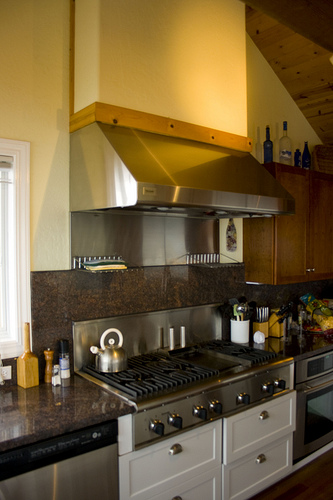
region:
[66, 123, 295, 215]
Silver range hood cover.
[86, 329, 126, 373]
Silver tea kettle with white handle.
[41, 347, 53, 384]
A brown pepper grinder.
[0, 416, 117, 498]
A black and silver dishwasher.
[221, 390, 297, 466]
A white drawer opened slightly.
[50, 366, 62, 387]
White salt shaker.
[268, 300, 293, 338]
A knife block with knives in it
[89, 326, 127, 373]
A stainless steel kettle with a white handle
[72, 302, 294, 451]
A large stainless steel cooktop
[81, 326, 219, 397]
A kettle sitting on a cooktop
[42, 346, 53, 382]
A wooden pepper mill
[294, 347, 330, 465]
A stainless steel oven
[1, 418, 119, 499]
A stainless steel dishwasher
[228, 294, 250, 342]
A white crock containing kitchen utensils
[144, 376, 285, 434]
Control knobs for a kitchen cooktop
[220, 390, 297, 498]
White kitchen drawers with stainless steel handles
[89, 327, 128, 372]
tea kettle on stove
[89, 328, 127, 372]
tea kettle is stainless steel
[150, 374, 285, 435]
black knobs on stove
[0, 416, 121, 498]
dishwasher is under counter top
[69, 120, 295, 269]
range hood over stove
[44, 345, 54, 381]
wooden grinder on counter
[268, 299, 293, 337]
knife block on counter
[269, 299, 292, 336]
knife block is wooden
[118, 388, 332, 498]
white wood under counter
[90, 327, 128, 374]
Silver kettle with white handle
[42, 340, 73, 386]
Salt and pepper shakers on the counter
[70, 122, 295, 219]
Fan over the stovetop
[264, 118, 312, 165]
Bottles above the cabinet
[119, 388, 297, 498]
White cabinets under the stove top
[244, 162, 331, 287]
Wooden cabinets over the oven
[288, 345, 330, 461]
Oven to the right of the stove top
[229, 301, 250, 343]
Utensils in a white jar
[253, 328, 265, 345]
White timer on the counter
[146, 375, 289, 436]
Control knobs for the stove top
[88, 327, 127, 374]
silver tea kettle with white handle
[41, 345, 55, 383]
brown wood pepper grinder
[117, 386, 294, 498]
four white drawers under a stove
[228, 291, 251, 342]
utensils in a white vase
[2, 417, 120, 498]
black and silver dishwasher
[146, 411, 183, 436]
two black knobs of a stove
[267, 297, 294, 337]
knives in a wood holder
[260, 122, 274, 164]
glass blue bottle with cork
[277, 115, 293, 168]
clear liquor bottle with blue top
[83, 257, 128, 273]
green and yellow pot holders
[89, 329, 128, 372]
the kettle is silver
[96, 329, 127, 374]
the kettle is metal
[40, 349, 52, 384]
the pepper shaker is wooden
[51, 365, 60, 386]
salt is on the counter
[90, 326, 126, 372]
the tea kettle is silver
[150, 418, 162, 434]
an stove temperature knob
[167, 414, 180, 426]
an stove temperature knob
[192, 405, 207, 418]
an stove temperature knob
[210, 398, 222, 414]
an stove temperature knob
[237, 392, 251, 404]
an stove temperature knob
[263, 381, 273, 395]
an stove temperature knob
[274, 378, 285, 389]
an stove temperature knob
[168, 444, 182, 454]
a chrome drawer handle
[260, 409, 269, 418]
a chrome drawer handle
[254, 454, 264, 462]
a chrome drawer handle